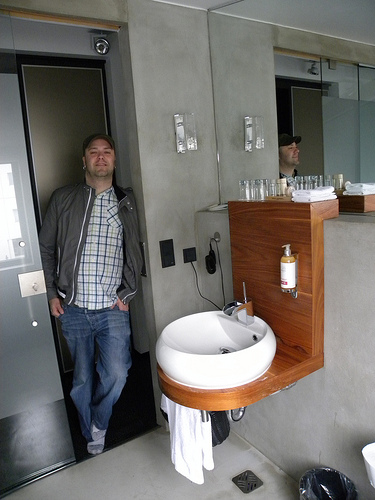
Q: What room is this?
A: Bathroom.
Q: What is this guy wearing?
A: Jeans.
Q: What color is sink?
A: White.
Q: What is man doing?
A: Leaning.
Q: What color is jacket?
A: Gray.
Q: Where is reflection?
A: In mirror.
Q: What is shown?
A: Sink.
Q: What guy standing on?
A: Door.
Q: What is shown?
A: Mirror.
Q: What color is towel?
A: White.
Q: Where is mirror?
A: On wall.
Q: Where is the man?
A: In the doorway.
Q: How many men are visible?
A: One.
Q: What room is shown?
A: Bathroom.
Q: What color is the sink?
A: White.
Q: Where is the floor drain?
A: Under the sink.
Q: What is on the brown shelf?
A: Toiletries.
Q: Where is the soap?
A: Above the sink.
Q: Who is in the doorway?
A: A man.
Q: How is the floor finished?
A: With tile.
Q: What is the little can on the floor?
A: A trash can.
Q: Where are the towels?
A: Hanging under the sink.